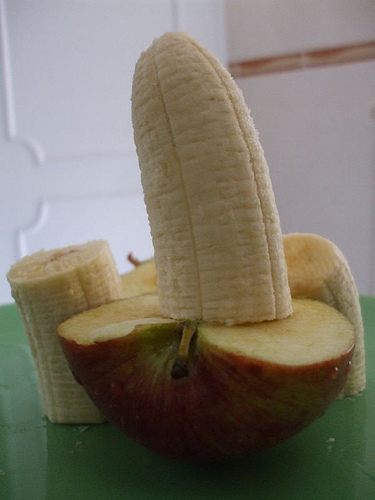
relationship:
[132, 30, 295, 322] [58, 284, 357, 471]
piece on top of apple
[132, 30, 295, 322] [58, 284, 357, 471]
piece on apple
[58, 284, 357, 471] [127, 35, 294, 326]
apple with bananas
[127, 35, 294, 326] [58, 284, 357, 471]
bananas on apple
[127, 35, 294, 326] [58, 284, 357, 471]
bananas on top of apple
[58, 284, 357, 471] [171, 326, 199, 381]
apple has stem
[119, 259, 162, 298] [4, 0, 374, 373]
apple in background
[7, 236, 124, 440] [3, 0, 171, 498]
piece on left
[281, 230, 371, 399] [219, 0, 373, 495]
piece on right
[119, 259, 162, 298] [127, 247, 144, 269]
apple has stem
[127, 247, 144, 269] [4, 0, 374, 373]
stem in background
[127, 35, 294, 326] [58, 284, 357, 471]
bananas stacked on apple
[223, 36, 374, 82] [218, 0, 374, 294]
sign on wall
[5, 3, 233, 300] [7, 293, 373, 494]
wall behind table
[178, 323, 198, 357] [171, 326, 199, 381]
ring around stem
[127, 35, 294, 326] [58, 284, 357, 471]
bananas next to apple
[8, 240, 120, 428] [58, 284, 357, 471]
banana behind apple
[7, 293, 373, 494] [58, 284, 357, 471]
table under apple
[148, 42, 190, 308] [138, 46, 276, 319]
line down side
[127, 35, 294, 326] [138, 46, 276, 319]
bananas has side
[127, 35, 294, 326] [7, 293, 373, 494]
bananas on table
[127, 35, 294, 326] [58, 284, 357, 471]
bananas standing on apple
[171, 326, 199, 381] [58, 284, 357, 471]
stem on apple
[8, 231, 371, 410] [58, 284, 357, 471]
bananas behind apple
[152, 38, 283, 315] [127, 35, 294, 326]
lines in bananas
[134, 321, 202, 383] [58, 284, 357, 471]
color on apple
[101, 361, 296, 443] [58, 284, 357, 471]
coloring on apple